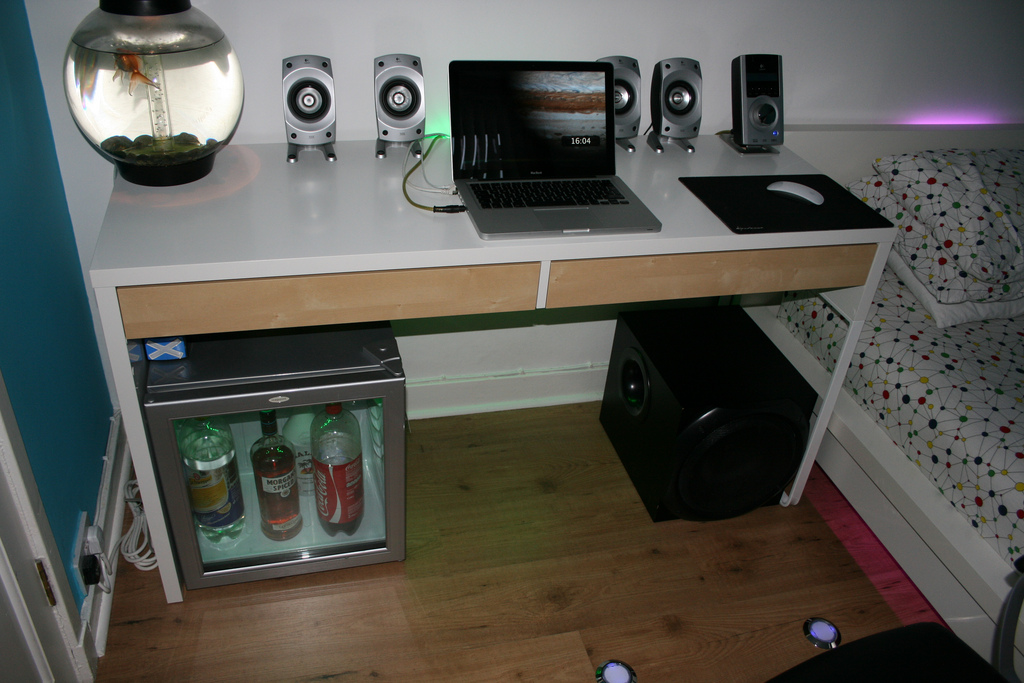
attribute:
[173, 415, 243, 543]
bottle — soda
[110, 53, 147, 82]
goldfish — swimming 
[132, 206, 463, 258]
desk — white 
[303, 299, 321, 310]
drawer — brown , wooden 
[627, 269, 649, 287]
drawer — brown , wooden 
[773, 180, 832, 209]
mouse — wireless 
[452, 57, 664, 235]
laptop — open 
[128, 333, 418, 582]
refrigerator — small 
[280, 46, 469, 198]
speakers — small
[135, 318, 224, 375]
flag — small, Scottish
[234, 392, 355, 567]
chest — drink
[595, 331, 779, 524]
sound system — black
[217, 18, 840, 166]
speaker system — small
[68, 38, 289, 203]
aquarium — cylindrical, for fish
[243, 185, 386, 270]
table — white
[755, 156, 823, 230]
mouse — white, cordless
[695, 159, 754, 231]
mouse pad — dark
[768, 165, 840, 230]
mouse — white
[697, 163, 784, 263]
mousepad — black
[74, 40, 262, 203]
fishbowl — glass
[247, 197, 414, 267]
table — white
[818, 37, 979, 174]
wall — white, flat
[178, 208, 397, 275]
table — long, white